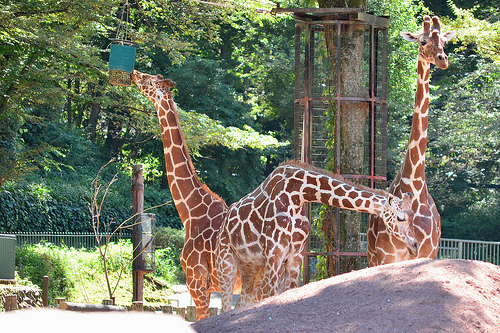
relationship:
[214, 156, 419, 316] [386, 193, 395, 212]
giraffe has ear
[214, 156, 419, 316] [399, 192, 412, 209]
giraffe has horn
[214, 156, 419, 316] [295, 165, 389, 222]
giraffe has neck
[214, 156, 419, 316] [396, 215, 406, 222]
giraffe has eye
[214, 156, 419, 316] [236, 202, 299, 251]
giraffe has spots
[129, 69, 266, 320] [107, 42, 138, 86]
giraffe eats from feeder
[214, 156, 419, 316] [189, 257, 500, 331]
giraffe licks rock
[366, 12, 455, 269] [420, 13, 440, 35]
giraffe has horns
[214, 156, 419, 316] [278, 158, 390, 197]
giraffe has mane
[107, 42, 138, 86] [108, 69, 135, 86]
feeder has food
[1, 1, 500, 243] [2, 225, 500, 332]
trees behind fence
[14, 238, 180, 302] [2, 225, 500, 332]
bushes before fence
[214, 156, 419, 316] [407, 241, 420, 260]
giraffe has nose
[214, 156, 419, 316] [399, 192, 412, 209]
giraffe has ossicles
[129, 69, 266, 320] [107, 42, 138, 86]
giraffe has feeder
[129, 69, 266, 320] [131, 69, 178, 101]
giraffe has head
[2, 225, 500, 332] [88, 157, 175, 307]
fence around tree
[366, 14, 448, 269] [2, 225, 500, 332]
giraffe in fence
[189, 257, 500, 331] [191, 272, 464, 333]
rock has shadow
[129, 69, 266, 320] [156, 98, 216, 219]
giraffe has neck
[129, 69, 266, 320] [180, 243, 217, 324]
giraffe has legs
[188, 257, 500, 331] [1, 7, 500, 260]
rock on ground